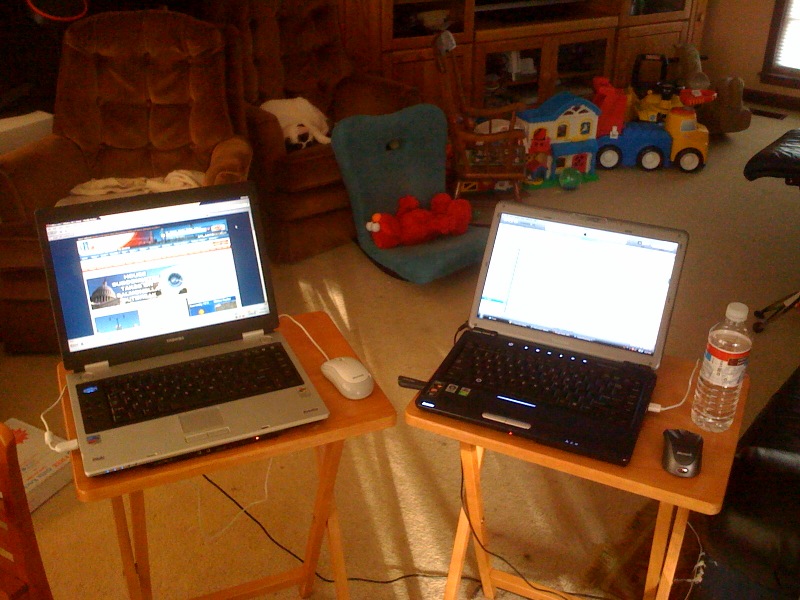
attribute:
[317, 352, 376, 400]
mouse — white, grey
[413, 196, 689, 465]
computer — laptop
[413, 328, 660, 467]
keyboard — black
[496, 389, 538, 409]
light — long, blue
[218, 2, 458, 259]
chair — reclining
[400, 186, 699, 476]
laptop — small